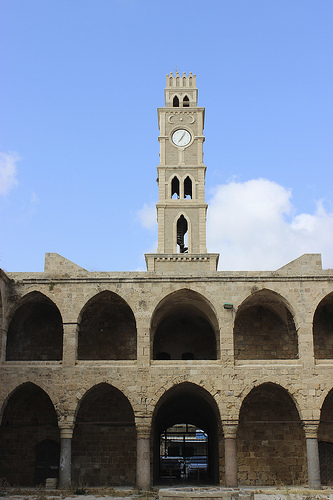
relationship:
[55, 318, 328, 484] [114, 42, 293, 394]
pillars in building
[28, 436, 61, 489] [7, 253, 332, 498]
door in building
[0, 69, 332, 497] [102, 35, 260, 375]
bricks on building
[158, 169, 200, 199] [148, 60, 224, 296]
arches part of building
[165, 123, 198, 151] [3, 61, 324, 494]
clock on top of building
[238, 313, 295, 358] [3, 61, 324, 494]
bricks on a building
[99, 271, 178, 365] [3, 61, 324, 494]
bricks on a building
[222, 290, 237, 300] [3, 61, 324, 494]
bricks on building